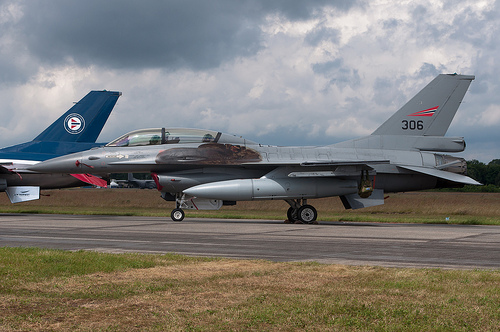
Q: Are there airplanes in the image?
A: Yes, there is an airplane.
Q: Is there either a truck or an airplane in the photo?
A: Yes, there is an airplane.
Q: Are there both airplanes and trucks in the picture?
A: No, there is an airplane but no trucks.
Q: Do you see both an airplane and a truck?
A: No, there is an airplane but no trucks.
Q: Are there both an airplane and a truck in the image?
A: No, there is an airplane but no trucks.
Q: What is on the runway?
A: The airplane is on the runway.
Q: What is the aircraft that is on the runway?
A: The aircraft is an airplane.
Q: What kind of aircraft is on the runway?
A: The aircraft is an airplane.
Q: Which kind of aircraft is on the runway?
A: The aircraft is an airplane.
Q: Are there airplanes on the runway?
A: Yes, there is an airplane on the runway.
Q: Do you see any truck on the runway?
A: No, there is an airplane on the runway.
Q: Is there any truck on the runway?
A: No, there is an airplane on the runway.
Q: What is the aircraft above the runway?
A: The aircraft is an airplane.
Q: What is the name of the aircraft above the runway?
A: The aircraft is an airplane.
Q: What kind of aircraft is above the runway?
A: The aircraft is an airplane.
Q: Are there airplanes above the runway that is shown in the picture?
A: Yes, there is an airplane above the runway.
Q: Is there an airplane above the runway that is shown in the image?
A: Yes, there is an airplane above the runway.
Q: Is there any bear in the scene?
A: No, there are no bears.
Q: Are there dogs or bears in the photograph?
A: No, there are no bears or dogs.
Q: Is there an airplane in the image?
A: Yes, there is an airplane.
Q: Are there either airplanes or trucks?
A: Yes, there is an airplane.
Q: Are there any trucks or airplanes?
A: Yes, there is an airplane.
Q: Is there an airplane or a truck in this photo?
A: Yes, there is an airplane.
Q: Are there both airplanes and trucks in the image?
A: No, there is an airplane but no trucks.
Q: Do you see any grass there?
A: Yes, there is grass.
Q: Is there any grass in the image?
A: Yes, there is grass.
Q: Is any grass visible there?
A: Yes, there is grass.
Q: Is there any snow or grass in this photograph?
A: Yes, there is grass.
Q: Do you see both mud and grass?
A: No, there is grass but no mud.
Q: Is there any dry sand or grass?
A: Yes, there is dry grass.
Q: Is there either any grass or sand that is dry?
A: Yes, the grass is dry.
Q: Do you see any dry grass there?
A: Yes, there is dry grass.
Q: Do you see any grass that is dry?
A: Yes, there is grass that is dry.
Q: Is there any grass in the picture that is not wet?
A: Yes, there is dry grass.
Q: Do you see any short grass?
A: Yes, there is short grass.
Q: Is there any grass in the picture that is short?
A: Yes, there is grass that is short.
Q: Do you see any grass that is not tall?
A: Yes, there is short grass.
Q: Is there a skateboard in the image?
A: No, there are no skateboards.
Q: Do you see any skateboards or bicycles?
A: No, there are no skateboards or bicycles.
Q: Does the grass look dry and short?
A: Yes, the grass is dry and short.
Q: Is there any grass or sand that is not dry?
A: No, there is grass but it is dry.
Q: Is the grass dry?
A: Yes, the grass is dry.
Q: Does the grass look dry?
A: Yes, the grass is dry.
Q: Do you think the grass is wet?
A: No, the grass is dry.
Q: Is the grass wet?
A: No, the grass is dry.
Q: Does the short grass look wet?
A: No, the grass is dry.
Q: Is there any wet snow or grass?
A: No, there is grass but it is dry.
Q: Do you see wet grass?
A: No, there is grass but it is dry.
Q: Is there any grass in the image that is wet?
A: No, there is grass but it is dry.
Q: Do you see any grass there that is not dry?
A: No, there is grass but it is dry.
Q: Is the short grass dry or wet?
A: The grass is dry.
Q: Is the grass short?
A: Yes, the grass is short.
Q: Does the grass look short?
A: Yes, the grass is short.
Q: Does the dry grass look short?
A: Yes, the grass is short.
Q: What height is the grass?
A: The grass is short.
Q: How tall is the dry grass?
A: The grass is short.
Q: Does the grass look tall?
A: No, the grass is short.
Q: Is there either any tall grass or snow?
A: No, there is grass but it is short.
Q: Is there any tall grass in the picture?
A: No, there is grass but it is short.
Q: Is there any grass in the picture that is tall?
A: No, there is grass but it is short.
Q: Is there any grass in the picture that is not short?
A: No, there is grass but it is short.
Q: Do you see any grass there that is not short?
A: No, there is grass but it is short.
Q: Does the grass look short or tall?
A: The grass is short.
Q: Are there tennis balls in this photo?
A: No, there are no tennis balls.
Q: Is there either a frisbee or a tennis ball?
A: No, there are no tennis balls or frisbees.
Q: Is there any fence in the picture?
A: No, there are no fences.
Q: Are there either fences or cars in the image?
A: No, there are no fences or cars.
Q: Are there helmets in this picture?
A: No, there are no helmets.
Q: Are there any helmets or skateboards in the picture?
A: No, there are no helmets or skateboards.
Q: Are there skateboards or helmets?
A: No, there are no helmets or skateboards.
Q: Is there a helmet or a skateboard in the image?
A: No, there are no helmets or skateboards.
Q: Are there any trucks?
A: No, there are no trucks.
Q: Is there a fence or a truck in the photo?
A: No, there are no trucks or fences.